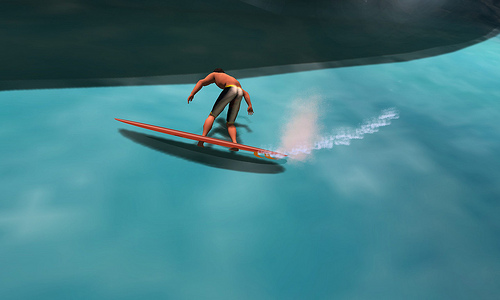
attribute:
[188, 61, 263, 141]
man — computer generated, crouching, bent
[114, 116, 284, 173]
surfboard — orange, red, brown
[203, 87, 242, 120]
shorts — gray, black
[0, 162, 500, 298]
water — computer generated, blue, cloudy, calm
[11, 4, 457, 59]
water — dark